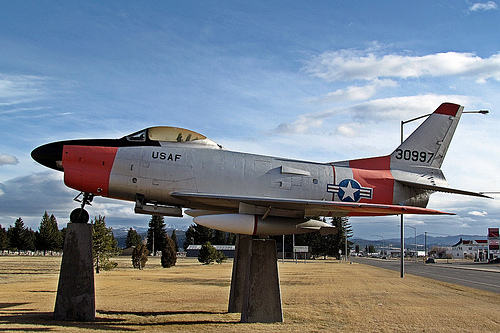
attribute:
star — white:
[340, 182, 359, 202]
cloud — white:
[303, 46, 497, 82]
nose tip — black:
[31, 142, 55, 169]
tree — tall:
[38, 213, 55, 258]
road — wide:
[347, 254, 499, 293]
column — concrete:
[242, 242, 284, 323]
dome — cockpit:
[127, 125, 204, 145]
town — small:
[451, 226, 499, 267]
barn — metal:
[188, 242, 235, 256]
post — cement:
[230, 235, 253, 316]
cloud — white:
[466, 2, 496, 17]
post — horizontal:
[465, 106, 480, 117]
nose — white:
[194, 211, 255, 236]